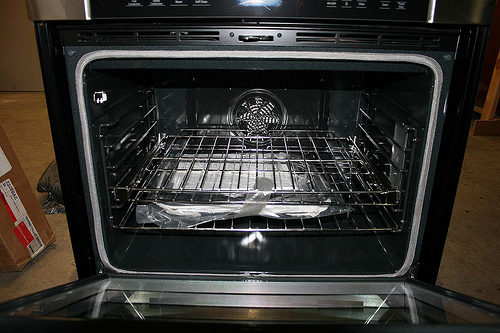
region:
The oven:
[160, 128, 255, 210]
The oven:
[292, 233, 352, 328]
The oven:
[232, 114, 314, 239]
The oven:
[212, 112, 350, 328]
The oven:
[238, 211, 299, 328]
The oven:
[233, 185, 273, 281]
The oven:
[261, 150, 321, 286]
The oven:
[300, 190, 320, 320]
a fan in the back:
[221, 87, 289, 157]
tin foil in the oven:
[128, 122, 364, 229]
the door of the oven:
[7, 242, 499, 332]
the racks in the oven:
[107, 112, 411, 245]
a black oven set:
[3, 2, 498, 332]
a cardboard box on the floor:
[0, 118, 63, 281]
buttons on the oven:
[317, 0, 417, 17]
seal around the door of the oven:
[76, 41, 436, 78]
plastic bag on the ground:
[27, 145, 84, 222]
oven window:
[62, 272, 469, 324]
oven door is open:
[36, 32, 460, 309]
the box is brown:
[0, 133, 96, 308]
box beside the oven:
[0, 134, 80, 283]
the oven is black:
[41, 20, 468, 325]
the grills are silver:
[131, 126, 406, 234]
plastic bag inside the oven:
[125, 152, 370, 223]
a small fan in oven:
[213, 93, 292, 130]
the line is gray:
[65, 45, 442, 288]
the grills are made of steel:
[138, 124, 343, 241]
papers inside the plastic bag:
[168, 144, 315, 221]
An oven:
[134, 66, 313, 319]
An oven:
[256, 217, 313, 321]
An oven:
[266, 153, 295, 238]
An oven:
[233, 97, 300, 248]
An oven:
[253, 142, 306, 292]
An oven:
[288, 116, 345, 326]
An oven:
[270, 157, 323, 296]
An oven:
[241, 93, 264, 142]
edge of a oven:
[271, 276, 301, 282]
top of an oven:
[201, 21, 218, 28]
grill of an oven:
[224, 126, 288, 190]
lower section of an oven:
[261, 163, 293, 164]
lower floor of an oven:
[255, 236, 275, 252]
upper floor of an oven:
[183, 52, 218, 100]